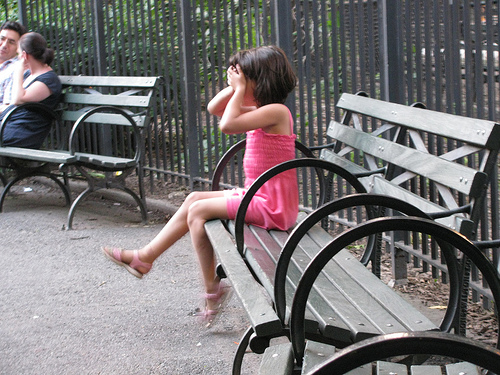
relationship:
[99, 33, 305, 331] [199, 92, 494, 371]
girl sitting on a bench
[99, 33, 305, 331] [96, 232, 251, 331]
girl wearing sandals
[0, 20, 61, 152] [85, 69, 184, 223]
man/woman on a bench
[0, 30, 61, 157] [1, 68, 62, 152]
woman wearing black dress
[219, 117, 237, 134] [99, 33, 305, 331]
elbow of a girl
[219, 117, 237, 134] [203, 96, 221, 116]
elbow of a elbow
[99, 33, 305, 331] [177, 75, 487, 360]
girl on bench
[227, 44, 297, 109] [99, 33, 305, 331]
hair on girl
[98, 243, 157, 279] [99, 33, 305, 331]
pink shoes on girl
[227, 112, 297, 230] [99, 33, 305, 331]
dress on girl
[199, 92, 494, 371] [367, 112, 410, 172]
bench on ground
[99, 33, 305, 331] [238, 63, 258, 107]
girl touching face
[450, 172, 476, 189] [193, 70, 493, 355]
bolt on bench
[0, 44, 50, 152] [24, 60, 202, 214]
couple on bench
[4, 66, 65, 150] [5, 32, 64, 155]
top on woman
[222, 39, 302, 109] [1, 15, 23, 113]
dark hair on man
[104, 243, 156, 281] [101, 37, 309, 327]
sandals on girl's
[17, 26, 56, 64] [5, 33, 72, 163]
hair on woman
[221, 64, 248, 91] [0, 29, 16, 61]
hand on face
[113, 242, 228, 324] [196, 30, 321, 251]
pink shoes on kid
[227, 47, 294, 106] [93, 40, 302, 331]
hair on kid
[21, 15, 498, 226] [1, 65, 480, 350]
fence near benches